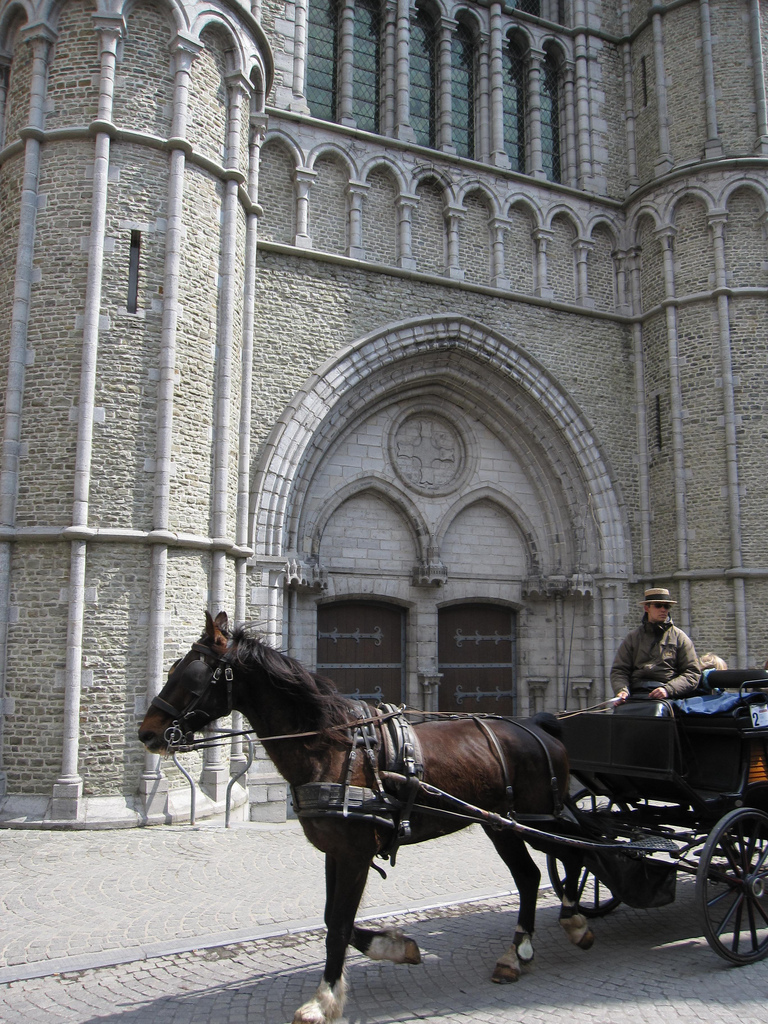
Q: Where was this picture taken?
A: On the street.